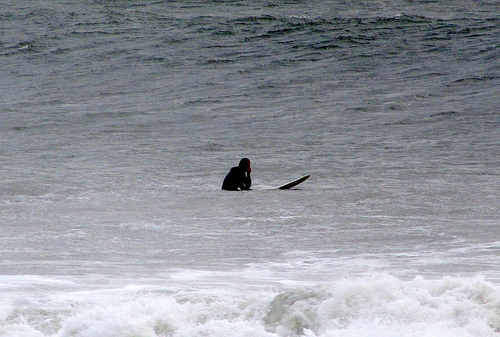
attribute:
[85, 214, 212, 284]
water — calm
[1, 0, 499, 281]
water — in the picture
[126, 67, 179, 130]
water — in the picture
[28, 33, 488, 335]
ocean — foamy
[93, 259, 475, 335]
wave — white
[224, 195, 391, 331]
waves — in the picture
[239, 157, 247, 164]
hair — in the picture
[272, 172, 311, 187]
board — in the picture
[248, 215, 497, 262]
water — in the picture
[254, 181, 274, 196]
foam — in the picture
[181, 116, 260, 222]
man — dressed 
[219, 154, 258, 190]
wet suit — black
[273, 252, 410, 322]
water — in the picture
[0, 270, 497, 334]
waves — white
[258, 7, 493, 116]
wave — in the picture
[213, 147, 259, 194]
surfer — in the picture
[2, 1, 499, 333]
ocean — in the picture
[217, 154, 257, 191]
surfer — in the picture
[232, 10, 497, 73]
wave — small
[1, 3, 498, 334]
water — in the picture